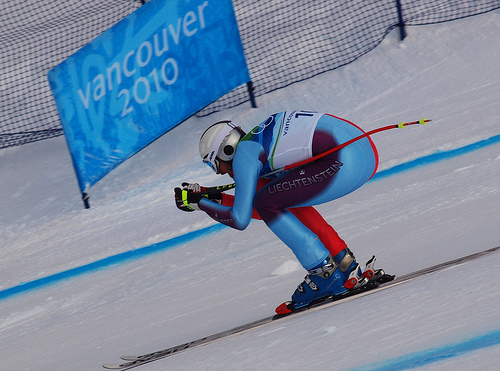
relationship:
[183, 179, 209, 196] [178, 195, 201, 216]
mans hand has strap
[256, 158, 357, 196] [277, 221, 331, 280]
word liechtenstein on leg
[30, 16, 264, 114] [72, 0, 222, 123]
sign says vancouver 2010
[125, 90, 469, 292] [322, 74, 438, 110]
scene on a slope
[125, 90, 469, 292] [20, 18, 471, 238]
scene happening during day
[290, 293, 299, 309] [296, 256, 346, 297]
edge of shoe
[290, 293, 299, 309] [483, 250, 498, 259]
edge of slide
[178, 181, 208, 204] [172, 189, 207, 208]
glove on hand